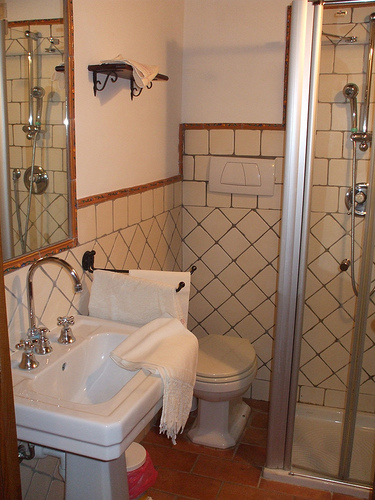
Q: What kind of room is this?
A: It is a bathroom.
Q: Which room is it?
A: It is a bathroom.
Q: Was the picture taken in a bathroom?
A: Yes, it was taken in a bathroom.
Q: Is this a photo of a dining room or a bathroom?
A: It is showing a bathroom.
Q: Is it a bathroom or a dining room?
A: It is a bathroom.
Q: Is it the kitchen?
A: No, it is the bathroom.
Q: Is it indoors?
A: Yes, it is indoors.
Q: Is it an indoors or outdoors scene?
A: It is indoors.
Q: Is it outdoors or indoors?
A: It is indoors.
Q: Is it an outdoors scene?
A: No, it is indoors.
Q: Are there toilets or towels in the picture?
A: Yes, there is a towel.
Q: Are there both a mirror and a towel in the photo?
A: Yes, there are both a towel and a mirror.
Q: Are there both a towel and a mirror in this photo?
A: Yes, there are both a towel and a mirror.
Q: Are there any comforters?
A: No, there are no comforters.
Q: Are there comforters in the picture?
A: No, there are no comforters.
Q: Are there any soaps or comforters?
A: No, there are no comforters or soaps.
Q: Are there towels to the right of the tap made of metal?
A: Yes, there is a towel to the right of the faucet.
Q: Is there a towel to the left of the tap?
A: No, the towel is to the right of the tap.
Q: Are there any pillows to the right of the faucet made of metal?
A: No, there is a towel to the right of the tap.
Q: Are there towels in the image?
A: Yes, there is a towel.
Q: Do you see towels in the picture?
A: Yes, there is a towel.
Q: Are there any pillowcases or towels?
A: Yes, there is a towel.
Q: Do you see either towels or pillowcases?
A: Yes, there is a towel.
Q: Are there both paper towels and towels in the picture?
A: No, there is a towel but no paper towels.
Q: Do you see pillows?
A: No, there are no pillows.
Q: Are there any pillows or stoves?
A: No, there are no pillows or stoves.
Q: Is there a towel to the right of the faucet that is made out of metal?
A: Yes, there is a towel to the right of the faucet.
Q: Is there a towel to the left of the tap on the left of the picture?
A: No, the towel is to the right of the faucet.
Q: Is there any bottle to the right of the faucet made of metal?
A: No, there is a towel to the right of the tap.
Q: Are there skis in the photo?
A: No, there are no skis.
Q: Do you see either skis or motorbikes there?
A: No, there are no skis or motorbikes.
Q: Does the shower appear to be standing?
A: Yes, the shower is standing.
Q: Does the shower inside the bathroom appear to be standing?
A: Yes, the shower is standing.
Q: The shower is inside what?
A: The shower is inside the bathroom.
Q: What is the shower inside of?
A: The shower is inside the bathroom.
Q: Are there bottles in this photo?
A: No, there are no bottles.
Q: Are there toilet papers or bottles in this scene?
A: No, there are no bottles or toilet papers.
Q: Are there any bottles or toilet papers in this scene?
A: No, there are no bottles or toilet papers.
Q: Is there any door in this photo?
A: Yes, there are doors.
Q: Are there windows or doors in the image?
A: Yes, there are doors.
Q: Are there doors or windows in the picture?
A: Yes, there are doors.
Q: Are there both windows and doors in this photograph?
A: No, there are doors but no windows.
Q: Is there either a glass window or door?
A: Yes, there are glass doors.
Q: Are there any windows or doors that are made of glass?
A: Yes, the doors are made of glass.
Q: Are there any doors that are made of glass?
A: Yes, there are doors that are made of glass.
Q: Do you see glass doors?
A: Yes, there are doors that are made of glass.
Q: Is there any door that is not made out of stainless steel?
A: Yes, there are doors that are made of glass.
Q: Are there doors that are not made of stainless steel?
A: Yes, there are doors that are made of glass.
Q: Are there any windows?
A: No, there are no windows.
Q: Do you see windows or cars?
A: No, there are no windows or cars.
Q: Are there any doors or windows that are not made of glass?
A: No, there are doors but they are made of glass.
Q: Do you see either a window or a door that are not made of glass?
A: No, there are doors but they are made of glass.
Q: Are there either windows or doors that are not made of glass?
A: No, there are doors but they are made of glass.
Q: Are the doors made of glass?
A: Yes, the doors are made of glass.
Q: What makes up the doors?
A: The doors are made of glass.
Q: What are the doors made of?
A: The doors are made of glass.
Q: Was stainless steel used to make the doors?
A: No, the doors are made of glass.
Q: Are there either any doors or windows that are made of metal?
A: No, there are doors but they are made of glass.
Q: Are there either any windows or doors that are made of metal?
A: No, there are doors but they are made of glass.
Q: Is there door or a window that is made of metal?
A: No, there are doors but they are made of glass.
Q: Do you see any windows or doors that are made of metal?
A: No, there are doors but they are made of glass.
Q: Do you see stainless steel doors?
A: No, there are doors but they are made of glass.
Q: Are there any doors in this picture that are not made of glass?
A: No, there are doors but they are made of glass.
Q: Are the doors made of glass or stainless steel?
A: The doors are made of glass.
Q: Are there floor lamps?
A: No, there are no floor lamps.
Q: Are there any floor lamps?
A: No, there are no floor lamps.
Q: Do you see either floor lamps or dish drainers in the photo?
A: No, there are no floor lamps or dish drainers.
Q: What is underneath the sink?
A: The pipes are underneath the sink.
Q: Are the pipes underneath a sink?
A: Yes, the pipes are underneath a sink.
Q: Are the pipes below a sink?
A: Yes, the pipes are below a sink.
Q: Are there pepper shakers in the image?
A: No, there are no pepper shakers.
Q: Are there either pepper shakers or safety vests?
A: No, there are no pepper shakers or safety vests.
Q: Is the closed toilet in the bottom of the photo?
A: Yes, the toilet is in the bottom of the image.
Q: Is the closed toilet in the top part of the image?
A: No, the toilet is in the bottom of the image.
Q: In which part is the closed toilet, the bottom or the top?
A: The toilet is in the bottom of the image.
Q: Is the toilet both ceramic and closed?
A: Yes, the toilet is ceramic and closed.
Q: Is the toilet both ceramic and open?
A: No, the toilet is ceramic but closed.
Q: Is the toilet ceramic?
A: Yes, the toilet is ceramic.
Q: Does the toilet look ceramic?
A: Yes, the toilet is ceramic.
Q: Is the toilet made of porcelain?
A: Yes, the toilet is made of porcelain.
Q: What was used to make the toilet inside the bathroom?
A: The toilet is made of porcelain.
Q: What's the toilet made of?
A: The toilet is made of porcelain.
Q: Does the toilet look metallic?
A: No, the toilet is ceramic.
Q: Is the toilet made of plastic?
A: No, the toilet is made of porcelain.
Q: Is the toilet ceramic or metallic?
A: The toilet is ceramic.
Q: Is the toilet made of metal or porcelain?
A: The toilet is made of porcelain.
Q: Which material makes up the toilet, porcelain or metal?
A: The toilet is made of porcelain.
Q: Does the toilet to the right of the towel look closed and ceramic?
A: Yes, the toilet is closed and ceramic.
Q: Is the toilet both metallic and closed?
A: No, the toilet is closed but ceramic.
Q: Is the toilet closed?
A: Yes, the toilet is closed.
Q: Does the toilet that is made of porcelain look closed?
A: Yes, the toilet is closed.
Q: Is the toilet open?
A: No, the toilet is closed.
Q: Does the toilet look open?
A: No, the toilet is closed.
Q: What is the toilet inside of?
A: The toilet is inside the bathroom.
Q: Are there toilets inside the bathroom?
A: Yes, there is a toilet inside the bathroom.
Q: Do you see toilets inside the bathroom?
A: Yes, there is a toilet inside the bathroom.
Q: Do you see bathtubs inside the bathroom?
A: No, there is a toilet inside the bathroom.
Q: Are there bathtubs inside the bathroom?
A: No, there is a toilet inside the bathroom.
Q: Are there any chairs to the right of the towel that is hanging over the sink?
A: No, there is a toilet to the right of the towel.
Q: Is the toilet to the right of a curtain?
A: No, the toilet is to the right of the towel.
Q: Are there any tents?
A: No, there are no tents.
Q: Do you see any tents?
A: No, there are no tents.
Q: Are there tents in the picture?
A: No, there are no tents.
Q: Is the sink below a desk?
A: No, the sink is below a mirror.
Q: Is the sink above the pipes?
A: Yes, the sink is above the pipes.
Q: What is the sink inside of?
A: The sink is inside the bathroom.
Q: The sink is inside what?
A: The sink is inside the bathroom.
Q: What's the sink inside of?
A: The sink is inside the bathroom.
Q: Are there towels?
A: Yes, there is a towel.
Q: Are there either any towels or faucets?
A: Yes, there is a towel.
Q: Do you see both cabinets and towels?
A: No, there is a towel but no cabinets.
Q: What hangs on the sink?
A: The towel hangs on the sink.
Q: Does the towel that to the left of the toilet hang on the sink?
A: Yes, the towel hangs on the sink.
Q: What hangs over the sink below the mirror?
A: The towel hangs over the sink.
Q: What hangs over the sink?
A: The towel hangs over the sink.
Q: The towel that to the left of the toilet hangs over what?
A: The towel hangs over the sink.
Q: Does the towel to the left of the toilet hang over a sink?
A: Yes, the towel hangs over a sink.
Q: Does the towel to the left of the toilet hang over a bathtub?
A: No, the towel hangs over a sink.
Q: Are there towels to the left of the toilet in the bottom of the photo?
A: Yes, there is a towel to the left of the toilet.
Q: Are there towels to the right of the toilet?
A: No, the towel is to the left of the toilet.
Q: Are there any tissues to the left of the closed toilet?
A: No, there is a towel to the left of the toilet.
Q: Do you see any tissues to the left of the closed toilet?
A: No, there is a towel to the left of the toilet.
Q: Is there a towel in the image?
A: Yes, there is a towel.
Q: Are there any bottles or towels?
A: Yes, there is a towel.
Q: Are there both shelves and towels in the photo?
A: Yes, there are both a towel and a shelf.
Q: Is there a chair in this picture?
A: No, there are no chairs.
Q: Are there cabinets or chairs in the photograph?
A: No, there are no chairs or cabinets.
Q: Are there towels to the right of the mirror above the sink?
A: Yes, there is a towel to the right of the mirror.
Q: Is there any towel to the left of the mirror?
A: No, the towel is to the right of the mirror.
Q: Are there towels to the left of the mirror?
A: No, the towel is to the right of the mirror.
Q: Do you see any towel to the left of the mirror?
A: No, the towel is to the right of the mirror.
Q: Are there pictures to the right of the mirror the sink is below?
A: No, there is a towel to the right of the mirror.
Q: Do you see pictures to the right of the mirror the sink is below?
A: No, there is a towel to the right of the mirror.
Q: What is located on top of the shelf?
A: The towel is on top of the shelf.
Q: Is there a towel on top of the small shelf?
A: Yes, there is a towel on top of the shelf.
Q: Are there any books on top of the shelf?
A: No, there is a towel on top of the shelf.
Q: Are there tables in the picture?
A: No, there are no tables.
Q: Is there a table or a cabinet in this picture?
A: No, there are no tables or cabinets.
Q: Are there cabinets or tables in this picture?
A: No, there are no tables or cabinets.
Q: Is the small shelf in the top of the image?
A: Yes, the shelf is in the top of the image.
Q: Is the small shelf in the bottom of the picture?
A: No, the shelf is in the top of the image.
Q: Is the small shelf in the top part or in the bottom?
A: The shelf is in the top of the image.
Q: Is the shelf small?
A: Yes, the shelf is small.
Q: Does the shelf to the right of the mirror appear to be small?
A: Yes, the shelf is small.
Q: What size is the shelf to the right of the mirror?
A: The shelf is small.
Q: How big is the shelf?
A: The shelf is small.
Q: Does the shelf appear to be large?
A: No, the shelf is small.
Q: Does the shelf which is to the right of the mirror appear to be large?
A: No, the shelf is small.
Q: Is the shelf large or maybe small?
A: The shelf is small.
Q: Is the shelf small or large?
A: The shelf is small.